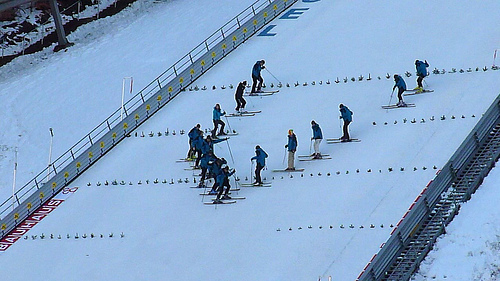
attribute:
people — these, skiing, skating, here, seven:
[193, 131, 282, 189]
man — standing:
[226, 83, 250, 109]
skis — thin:
[229, 110, 255, 117]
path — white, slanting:
[321, 32, 361, 55]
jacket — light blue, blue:
[186, 131, 198, 148]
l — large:
[254, 24, 283, 37]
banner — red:
[8, 203, 53, 221]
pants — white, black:
[215, 188, 226, 194]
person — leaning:
[244, 137, 285, 182]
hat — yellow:
[287, 129, 295, 133]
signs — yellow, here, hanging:
[227, 22, 253, 37]